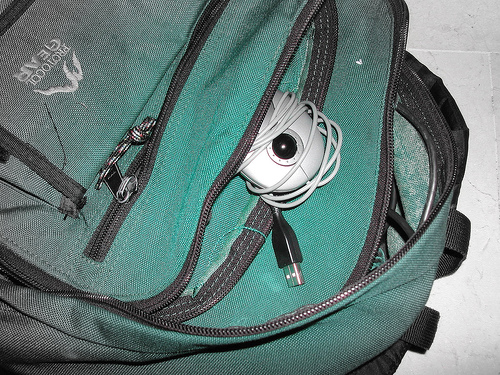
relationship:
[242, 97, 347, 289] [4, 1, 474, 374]
mouse sticking out of backpack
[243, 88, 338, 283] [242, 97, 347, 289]
cord wrapped around mouse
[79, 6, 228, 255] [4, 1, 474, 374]
zipper attached to backpack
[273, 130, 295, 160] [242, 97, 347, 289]
ball on mouse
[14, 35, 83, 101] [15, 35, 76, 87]
emblem reads protocol gear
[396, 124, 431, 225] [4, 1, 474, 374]
dirt inside of backpack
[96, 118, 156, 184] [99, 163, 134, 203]
rope attached to zipper handle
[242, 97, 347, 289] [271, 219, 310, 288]
mouse has usb connector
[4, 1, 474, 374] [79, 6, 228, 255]
backpack has zipper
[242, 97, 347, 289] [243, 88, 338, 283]
mouse wrapped in cord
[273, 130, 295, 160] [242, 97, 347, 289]
ball attached to mouse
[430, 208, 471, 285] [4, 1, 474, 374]
strap attached to backpack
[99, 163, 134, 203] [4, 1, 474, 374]
zipper handle attached to backpack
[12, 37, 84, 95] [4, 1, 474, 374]
emblem sewn onto backpack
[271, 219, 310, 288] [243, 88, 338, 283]
usb connector attached to cord